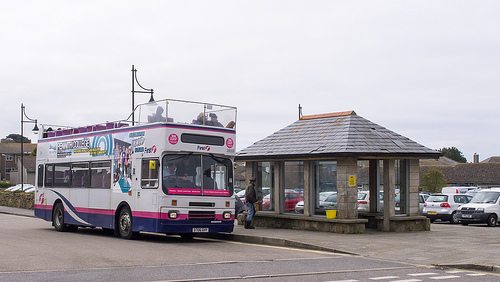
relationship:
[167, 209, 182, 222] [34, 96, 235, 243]
headlight on bus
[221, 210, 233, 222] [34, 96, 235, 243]
headlight on bus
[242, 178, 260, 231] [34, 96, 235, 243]
man near bus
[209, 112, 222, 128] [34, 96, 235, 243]
person on bus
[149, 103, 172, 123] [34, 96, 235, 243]
person on bus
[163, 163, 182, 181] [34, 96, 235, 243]
driver of bus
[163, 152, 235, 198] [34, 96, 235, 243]
windshield of bus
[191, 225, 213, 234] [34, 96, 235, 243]
license plate on bus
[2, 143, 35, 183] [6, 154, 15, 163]
building has windows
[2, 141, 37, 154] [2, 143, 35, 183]
roof on building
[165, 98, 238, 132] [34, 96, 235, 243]
window on bus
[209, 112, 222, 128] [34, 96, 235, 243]
person riding on bus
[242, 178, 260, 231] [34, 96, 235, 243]
man next to bus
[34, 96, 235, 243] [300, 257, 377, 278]
bus on pavement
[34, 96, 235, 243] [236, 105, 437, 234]
bus at bus stop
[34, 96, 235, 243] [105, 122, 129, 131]
bus has seats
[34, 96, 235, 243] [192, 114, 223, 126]
bus carrying people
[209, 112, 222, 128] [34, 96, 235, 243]
person on top of bus